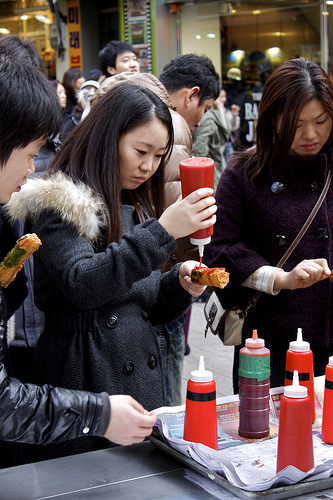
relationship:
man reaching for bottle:
[107, 41, 137, 70] [188, 369, 217, 435]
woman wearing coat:
[31, 83, 218, 462] [5, 168, 193, 396]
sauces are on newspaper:
[180, 320, 330, 469] [237, 445, 256, 470]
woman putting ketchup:
[201, 55, 332, 397] [191, 257, 226, 275]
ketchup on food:
[191, 257, 226, 275] [195, 264, 231, 293]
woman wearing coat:
[31, 83, 218, 462] [64, 249, 155, 373]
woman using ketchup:
[31, 83, 218, 462] [183, 374, 221, 442]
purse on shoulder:
[198, 170, 331, 346] [43, 191, 86, 221]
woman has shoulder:
[201, 50, 331, 388] [43, 191, 86, 221]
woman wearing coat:
[31, 83, 218, 462] [0, 172, 180, 462]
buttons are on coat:
[79, 422, 95, 440] [0, 172, 180, 462]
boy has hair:
[0, 29, 163, 449] [0, 38, 65, 163]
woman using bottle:
[22, 80, 208, 425] [226, 339, 270, 427]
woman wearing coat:
[67, 73, 84, 86] [204, 135, 331, 381]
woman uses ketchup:
[31, 83, 218, 462] [181, 154, 214, 267]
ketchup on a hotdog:
[181, 154, 214, 267] [191, 266, 229, 289]